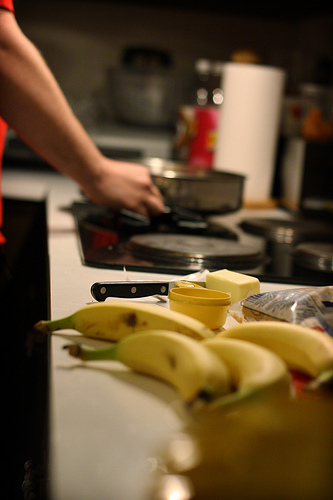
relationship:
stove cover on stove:
[129, 229, 266, 266] [72, 203, 331, 285]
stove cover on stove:
[129, 234, 260, 266] [72, 203, 331, 285]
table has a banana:
[0, 167, 193, 499] [53, 295, 215, 353]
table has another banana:
[44, 266, 331, 496] [60, 324, 234, 407]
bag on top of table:
[244, 286, 331, 326] [47, 273, 178, 456]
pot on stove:
[141, 163, 245, 221] [38, 178, 331, 285]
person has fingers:
[0, 0, 173, 252] [134, 169, 164, 218]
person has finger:
[0, 0, 173, 252] [139, 190, 166, 215]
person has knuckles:
[0, 0, 168, 252] [121, 160, 156, 216]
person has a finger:
[0, 0, 168, 252] [145, 182, 178, 220]